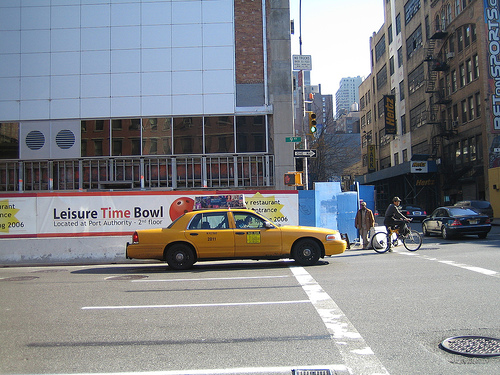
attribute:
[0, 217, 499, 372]
street — city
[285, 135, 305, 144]
street sign — green-and-white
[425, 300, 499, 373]
metal —  grates, circular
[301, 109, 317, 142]
light — green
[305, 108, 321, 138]
traffic light — green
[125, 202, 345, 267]
taxicab — yellow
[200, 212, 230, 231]
rear window — rear cab 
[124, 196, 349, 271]
taxi — yellow 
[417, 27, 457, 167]
fire escape — Black 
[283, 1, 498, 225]
different buildings — several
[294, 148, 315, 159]
street sign — one-way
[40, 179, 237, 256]
panel — white , red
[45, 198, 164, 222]
lettering — black 